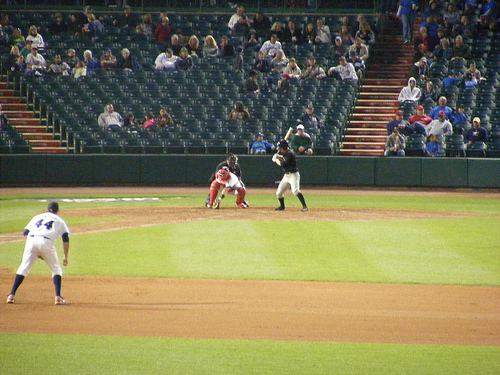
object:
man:
[271, 138, 309, 213]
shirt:
[278, 149, 296, 172]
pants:
[275, 170, 301, 197]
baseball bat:
[275, 127, 293, 153]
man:
[4, 200, 74, 305]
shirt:
[23, 211, 69, 239]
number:
[43, 219, 56, 229]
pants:
[16, 236, 63, 278]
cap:
[48, 200, 58, 212]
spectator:
[432, 96, 452, 119]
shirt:
[431, 105, 451, 120]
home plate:
[251, 207, 273, 212]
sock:
[279, 197, 286, 207]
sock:
[296, 193, 308, 209]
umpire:
[212, 154, 243, 180]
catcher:
[203, 168, 251, 209]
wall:
[0, 155, 500, 191]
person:
[290, 124, 314, 154]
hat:
[295, 123, 304, 129]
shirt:
[291, 133, 312, 151]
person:
[117, 48, 140, 70]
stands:
[0, 3, 499, 156]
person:
[397, 75, 421, 102]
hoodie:
[397, 76, 420, 102]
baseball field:
[0, 187, 499, 375]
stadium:
[0, 0, 500, 374]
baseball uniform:
[270, 140, 308, 212]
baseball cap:
[213, 168, 228, 182]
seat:
[98, 137, 120, 146]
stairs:
[25, 139, 71, 147]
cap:
[469, 114, 481, 124]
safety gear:
[204, 168, 247, 209]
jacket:
[447, 111, 468, 124]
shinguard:
[236, 186, 246, 204]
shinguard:
[207, 182, 220, 204]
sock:
[52, 274, 64, 297]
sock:
[11, 273, 24, 294]